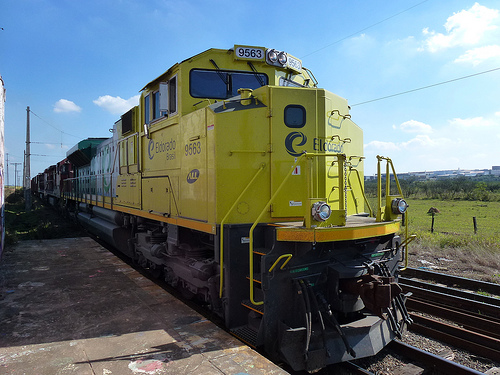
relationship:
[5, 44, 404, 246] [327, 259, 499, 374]
train on tracks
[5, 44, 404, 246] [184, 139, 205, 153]
train with number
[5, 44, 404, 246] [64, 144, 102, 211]
train with train cars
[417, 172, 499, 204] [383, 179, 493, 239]
tree in grass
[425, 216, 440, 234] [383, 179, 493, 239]
post in grass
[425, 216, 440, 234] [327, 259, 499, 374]
post next to tracks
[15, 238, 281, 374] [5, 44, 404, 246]
platform next to train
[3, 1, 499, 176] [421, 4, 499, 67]
sky with clouds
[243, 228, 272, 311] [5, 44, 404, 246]
stairs on train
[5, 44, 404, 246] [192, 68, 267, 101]
train with window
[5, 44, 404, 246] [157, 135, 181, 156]
train with word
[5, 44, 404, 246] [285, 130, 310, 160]
train with logo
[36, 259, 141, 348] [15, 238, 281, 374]
paint on platform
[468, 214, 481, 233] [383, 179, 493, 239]
post in grass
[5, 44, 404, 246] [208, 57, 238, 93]
train with windshield wipers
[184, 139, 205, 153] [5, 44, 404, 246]
number on train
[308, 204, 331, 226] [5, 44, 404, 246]
headlight on front of train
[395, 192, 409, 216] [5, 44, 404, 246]
headlight on front of train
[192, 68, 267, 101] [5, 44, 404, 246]
window on train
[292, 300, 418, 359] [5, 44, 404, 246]
cattle guard on train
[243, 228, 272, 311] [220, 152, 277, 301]
stairs with rails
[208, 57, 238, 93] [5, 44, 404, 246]
windshield wipers on train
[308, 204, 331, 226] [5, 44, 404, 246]
headlight on train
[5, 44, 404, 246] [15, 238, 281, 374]
train next to platform